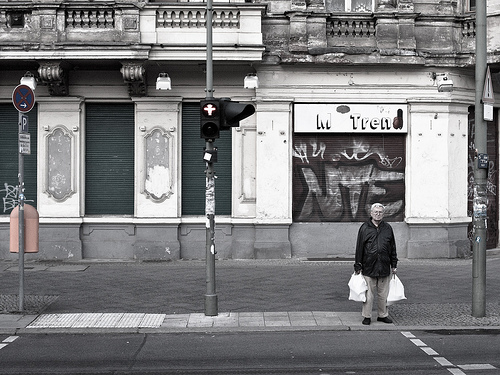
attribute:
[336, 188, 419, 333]
person — waiting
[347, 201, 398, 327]
man — older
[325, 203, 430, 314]
man — standing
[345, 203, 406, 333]
man — older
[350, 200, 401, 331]
man — mature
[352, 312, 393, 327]
shoes — black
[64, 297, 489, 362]
street — dark gray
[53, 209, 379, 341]
sidewalk — paved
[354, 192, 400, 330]
person — carrying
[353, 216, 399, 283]
coat — dark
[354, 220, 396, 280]
coat — black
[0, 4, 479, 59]
railings — black, white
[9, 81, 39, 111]
sign — red, blue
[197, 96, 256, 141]
fixture — black